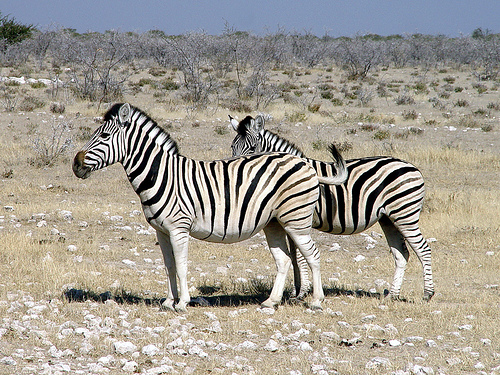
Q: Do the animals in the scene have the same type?
A: Yes, all the animals are zebras.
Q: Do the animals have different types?
A: No, all the animals are zebras.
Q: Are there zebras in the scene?
A: Yes, there is a zebra.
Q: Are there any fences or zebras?
A: Yes, there is a zebra.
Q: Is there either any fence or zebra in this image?
A: Yes, there is a zebra.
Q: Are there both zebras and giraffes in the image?
A: No, there is a zebra but no giraffes.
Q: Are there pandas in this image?
A: No, there are no pandas.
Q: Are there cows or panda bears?
A: No, there are no panda bears or cows.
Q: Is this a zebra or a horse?
A: This is a zebra.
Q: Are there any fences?
A: No, there are no fences.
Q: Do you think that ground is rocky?
A: Yes, the ground is rocky.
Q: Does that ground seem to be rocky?
A: Yes, the ground is rocky.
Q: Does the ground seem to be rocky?
A: Yes, the ground is rocky.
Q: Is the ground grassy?
A: No, the ground is rocky.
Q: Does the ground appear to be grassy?
A: No, the ground is rocky.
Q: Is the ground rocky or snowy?
A: The ground is rocky.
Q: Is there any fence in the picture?
A: No, there are no fences.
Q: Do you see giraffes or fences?
A: No, there are no fences or giraffes.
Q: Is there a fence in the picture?
A: No, there are no fences.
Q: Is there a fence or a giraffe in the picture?
A: No, there are no fences or giraffes.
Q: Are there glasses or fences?
A: No, there are no fences or glasses.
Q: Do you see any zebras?
A: Yes, there is a zebra.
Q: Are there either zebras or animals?
A: Yes, there is a zebra.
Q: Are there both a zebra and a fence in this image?
A: No, there is a zebra but no fences.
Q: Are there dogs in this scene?
A: No, there are no dogs.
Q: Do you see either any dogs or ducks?
A: No, there are no dogs or ducks.